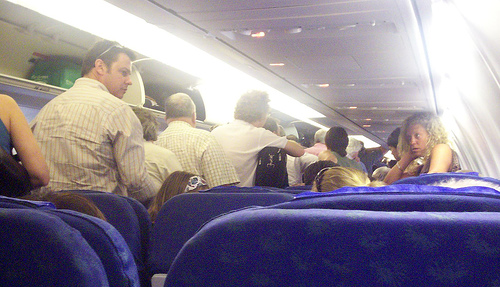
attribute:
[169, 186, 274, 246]
seat — blue, dark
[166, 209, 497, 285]
seat back — dark, blue 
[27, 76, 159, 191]
shirt — white, long sleeved, striped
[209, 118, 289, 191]
white shirt — white 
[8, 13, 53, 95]
compartment — overhead 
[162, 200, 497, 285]
seat — purple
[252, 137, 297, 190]
bag — black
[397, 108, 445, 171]
hair — curly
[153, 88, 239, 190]
man — older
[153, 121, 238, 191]
shirt — checkered 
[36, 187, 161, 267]
saet — dark, blue 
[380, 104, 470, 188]
woman — blond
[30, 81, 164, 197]
shirt — striped